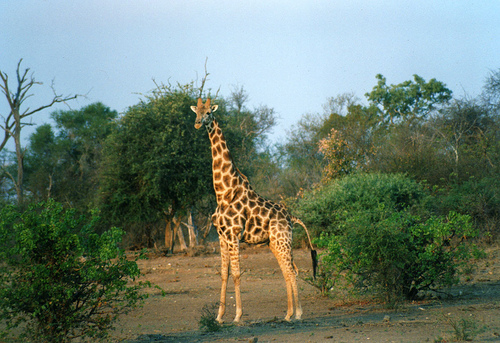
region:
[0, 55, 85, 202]
The tree is leafless.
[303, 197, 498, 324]
The bush is green.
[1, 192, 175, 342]
The bush is leafy.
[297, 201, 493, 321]
The bush is leafy.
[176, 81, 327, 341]
The giraffe is alert.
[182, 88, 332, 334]
The giraffe is tall.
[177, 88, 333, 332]
The giraffe is alone.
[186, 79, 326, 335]
The giraffe is brown and tan.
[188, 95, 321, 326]
Giraffe standing in the woods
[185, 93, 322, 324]
Brown and tan giraffe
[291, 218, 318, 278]
Giraffe tail with black hair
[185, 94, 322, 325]
Giraffe standing in the dirt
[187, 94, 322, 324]
Giraffe standing between bushes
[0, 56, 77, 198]
Two dead trees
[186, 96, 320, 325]
Tall giraffe standing outside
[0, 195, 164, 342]
Small tree with green leaves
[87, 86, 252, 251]
Dense tree with green leaves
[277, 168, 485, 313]
Smaller dense tree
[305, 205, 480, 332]
The bush is green.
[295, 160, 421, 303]
The bush is green.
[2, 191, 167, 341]
The bush is green.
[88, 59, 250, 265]
The tree is green.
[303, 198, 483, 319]
The bush is leafy.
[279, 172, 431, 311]
The bush is leafy.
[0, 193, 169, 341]
The bush is leafy.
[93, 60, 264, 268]
The tree is leafy.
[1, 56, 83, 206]
The tree is bare.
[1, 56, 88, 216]
The tree is leafless.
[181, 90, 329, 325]
giraffe standing in dirt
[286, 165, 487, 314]
bush in dirt with green leafs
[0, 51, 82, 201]
brown tree branches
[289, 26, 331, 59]
clear blue sky with light clouds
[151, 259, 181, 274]
small rocks in dirt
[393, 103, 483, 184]
several bushes and trees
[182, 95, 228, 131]
head of giraffe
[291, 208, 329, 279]
tail of giraffe with hair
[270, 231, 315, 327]
two back legs of giraffe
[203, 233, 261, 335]
two front legs of giraffe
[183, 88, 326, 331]
a big giraffe on a road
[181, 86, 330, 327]
giraffe is color brown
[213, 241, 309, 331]
legs of giraffe are long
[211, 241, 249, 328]
front legs of giraffe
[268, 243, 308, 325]
back legs of giraffe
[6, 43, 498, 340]
green trees around the giraffe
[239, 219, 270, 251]
belly of giraffe is bulky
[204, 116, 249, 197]
long neck of giraffe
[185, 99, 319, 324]
a giraffe standing in the dirt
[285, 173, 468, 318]
a bush in a field of dirt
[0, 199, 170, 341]
bush in a field of dirt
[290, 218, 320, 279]
a tail on a giraffe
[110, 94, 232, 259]
a tree in a field of dirt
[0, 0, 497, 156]
a clear blue sky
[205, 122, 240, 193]
a long neck on a giraffe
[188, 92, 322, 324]
a giraffe that is looking at the camera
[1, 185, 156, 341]
a lush green bush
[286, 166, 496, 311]
a lush green bush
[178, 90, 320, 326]
a giraffe that is standing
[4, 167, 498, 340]
a giraffe standing between two bushes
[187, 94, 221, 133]
the head of a giraffe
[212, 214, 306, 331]
the legs of a giraffe